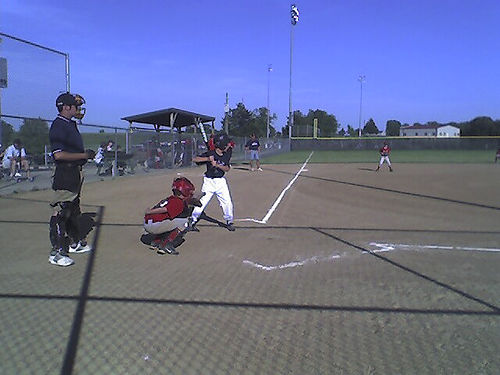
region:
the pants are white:
[201, 177, 235, 220]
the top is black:
[197, 152, 237, 180]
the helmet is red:
[168, 174, 203, 193]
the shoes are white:
[45, 244, 93, 276]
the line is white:
[268, 165, 299, 217]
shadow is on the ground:
[71, 271, 91, 343]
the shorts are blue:
[251, 152, 258, 162]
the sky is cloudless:
[131, 17, 241, 73]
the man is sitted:
[1, 138, 34, 178]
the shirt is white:
[8, 146, 30, 162]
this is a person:
[47, 86, 92, 277]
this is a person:
[141, 175, 201, 253]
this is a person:
[193, 135, 235, 233]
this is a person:
[246, 130, 263, 170]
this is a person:
[376, 138, 393, 171]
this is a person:
[241, 246, 270, 281]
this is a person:
[238, 212, 260, 230]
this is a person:
[263, 184, 293, 221]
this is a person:
[298, 154, 314, 182]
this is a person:
[226, 290, 356, 325]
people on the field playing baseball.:
[35, 69, 458, 275]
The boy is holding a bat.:
[179, 108, 214, 142]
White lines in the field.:
[273, 145, 343, 285]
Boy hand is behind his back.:
[138, 200, 162, 225]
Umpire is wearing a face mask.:
[63, 89, 100, 128]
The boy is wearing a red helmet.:
[165, 175, 192, 193]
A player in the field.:
[365, 139, 410, 176]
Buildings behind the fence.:
[353, 107, 465, 142]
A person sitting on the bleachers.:
[4, 131, 32, 186]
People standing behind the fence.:
[110, 120, 208, 166]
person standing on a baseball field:
[30, 85, 107, 275]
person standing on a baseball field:
[187, 115, 244, 239]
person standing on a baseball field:
[243, 130, 265, 177]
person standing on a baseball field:
[372, 139, 397, 175]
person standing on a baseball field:
[135, 172, 217, 260]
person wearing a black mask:
[39, 85, 101, 271]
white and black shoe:
[40, 242, 76, 274]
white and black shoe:
[64, 234, 94, 256]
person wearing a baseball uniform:
[372, 139, 397, 175]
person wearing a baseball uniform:
[179, 117, 244, 232]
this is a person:
[127, 150, 202, 282]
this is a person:
[181, 112, 264, 267]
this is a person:
[353, 124, 420, 189]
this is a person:
[0, 131, 29, 192]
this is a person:
[87, 137, 121, 186]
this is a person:
[102, 133, 124, 169]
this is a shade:
[108, 88, 202, 153]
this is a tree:
[286, 84, 337, 143]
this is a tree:
[213, 90, 279, 158]